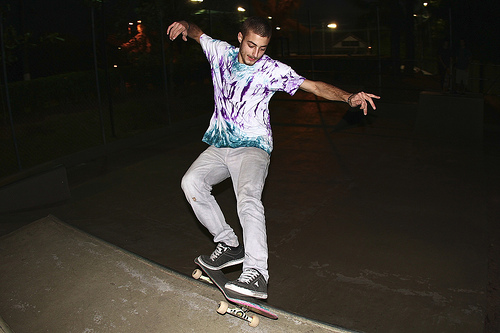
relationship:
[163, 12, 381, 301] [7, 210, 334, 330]
man on top f concrete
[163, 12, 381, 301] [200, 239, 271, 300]
man wearing sneakers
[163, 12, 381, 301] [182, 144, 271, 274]
man wearing jeans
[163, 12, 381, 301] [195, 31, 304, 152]
man wearing shirt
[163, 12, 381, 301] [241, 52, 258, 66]
man has facial hair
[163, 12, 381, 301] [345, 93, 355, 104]
man wearing wristwatch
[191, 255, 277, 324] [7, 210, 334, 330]
skateboard on top of concrete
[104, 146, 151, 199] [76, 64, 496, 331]
shadow on ground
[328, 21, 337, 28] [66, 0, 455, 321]
light behind skate park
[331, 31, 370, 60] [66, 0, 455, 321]
house behind skate park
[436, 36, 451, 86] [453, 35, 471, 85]
kid standing next to kid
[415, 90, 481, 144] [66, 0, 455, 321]
ramp in skate park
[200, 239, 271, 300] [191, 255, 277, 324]
sneakers on top of skateboard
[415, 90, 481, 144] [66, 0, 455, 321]
ramp at skate park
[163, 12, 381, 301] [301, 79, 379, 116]
man has arm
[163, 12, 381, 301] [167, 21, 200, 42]
man has arm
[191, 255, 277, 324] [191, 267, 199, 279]
skateboard has wheel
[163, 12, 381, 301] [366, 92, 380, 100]
man has finger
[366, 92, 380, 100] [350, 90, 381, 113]
finger on hand